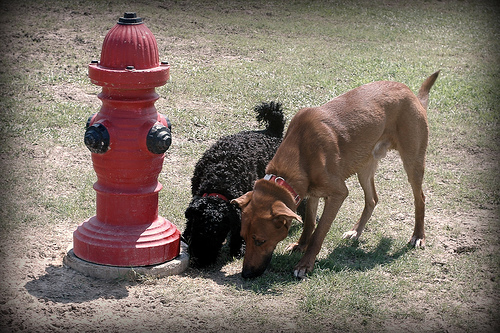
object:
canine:
[182, 97, 288, 267]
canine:
[231, 67, 440, 278]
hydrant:
[72, 11, 180, 265]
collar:
[196, 190, 231, 202]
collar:
[263, 173, 304, 207]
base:
[63, 237, 192, 281]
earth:
[4, 3, 499, 331]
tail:
[251, 101, 289, 136]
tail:
[413, 69, 441, 111]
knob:
[146, 123, 171, 154]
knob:
[85, 123, 106, 154]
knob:
[84, 118, 88, 137]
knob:
[166, 117, 171, 133]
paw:
[226, 243, 240, 258]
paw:
[290, 256, 319, 278]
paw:
[284, 242, 302, 255]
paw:
[342, 230, 363, 248]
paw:
[408, 232, 426, 250]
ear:
[182, 200, 206, 240]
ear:
[224, 203, 241, 239]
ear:
[230, 193, 252, 212]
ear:
[271, 200, 304, 227]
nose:
[192, 257, 207, 267]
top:
[100, 12, 160, 69]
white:
[261, 172, 274, 183]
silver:
[272, 176, 286, 184]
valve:
[115, 11, 145, 26]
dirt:
[99, 288, 211, 322]